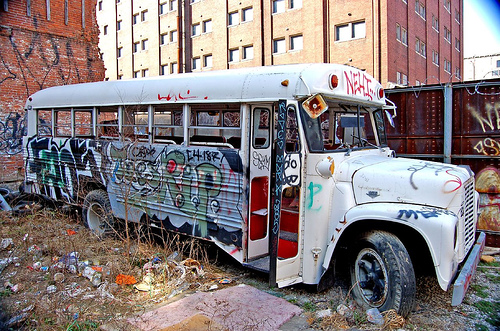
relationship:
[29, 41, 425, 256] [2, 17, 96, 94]
bus with graffiti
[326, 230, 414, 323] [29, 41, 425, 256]
wheel of bus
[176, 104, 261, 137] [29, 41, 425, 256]
window on bus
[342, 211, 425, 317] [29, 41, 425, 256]
tire of bus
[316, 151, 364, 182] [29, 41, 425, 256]
headlight of bus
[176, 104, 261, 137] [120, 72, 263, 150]
window on side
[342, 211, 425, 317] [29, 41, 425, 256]
tire on bus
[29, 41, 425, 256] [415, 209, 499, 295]
bus has bumper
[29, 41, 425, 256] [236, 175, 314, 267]
bus has door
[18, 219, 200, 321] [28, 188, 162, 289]
trash on ground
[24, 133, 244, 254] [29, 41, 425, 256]
graffiti on bus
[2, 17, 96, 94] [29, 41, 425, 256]
graffiti on bus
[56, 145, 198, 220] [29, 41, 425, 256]
graffiti on bus